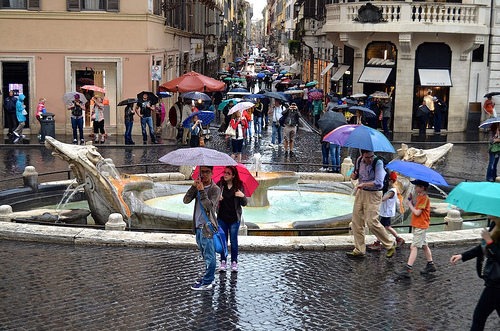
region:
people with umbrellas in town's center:
[86, 69, 443, 316]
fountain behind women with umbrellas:
[58, 139, 349, 280]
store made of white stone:
[307, 3, 478, 140]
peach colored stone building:
[10, 2, 186, 137]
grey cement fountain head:
[33, 129, 171, 236]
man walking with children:
[317, 123, 454, 276]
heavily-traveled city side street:
[190, 7, 330, 162]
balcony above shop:
[324, 1, 499, 71]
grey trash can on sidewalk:
[35, 111, 66, 148]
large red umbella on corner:
[149, 64, 239, 143]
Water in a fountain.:
[246, 141, 272, 180]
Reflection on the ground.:
[223, 246, 290, 329]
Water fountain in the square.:
[0, 134, 497, 251]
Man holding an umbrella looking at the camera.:
[159, 147, 223, 290]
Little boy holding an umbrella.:
[394, 157, 451, 276]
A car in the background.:
[239, 50, 261, 72]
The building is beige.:
[6, 5, 173, 136]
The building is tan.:
[316, 5, 498, 134]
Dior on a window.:
[76, 58, 111, 82]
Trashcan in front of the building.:
[31, 110, 66, 144]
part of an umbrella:
[205, 144, 208, 157]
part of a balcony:
[438, 15, 450, 66]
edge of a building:
[408, 70, 413, 102]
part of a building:
[80, 41, 114, 48]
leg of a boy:
[403, 250, 417, 265]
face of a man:
[366, 133, 378, 157]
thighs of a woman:
[225, 227, 239, 237]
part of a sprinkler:
[277, 173, 289, 199]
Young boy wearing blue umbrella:
[384, 158, 449, 284]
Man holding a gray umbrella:
[152, 142, 229, 299]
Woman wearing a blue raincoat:
[10, 89, 30, 141]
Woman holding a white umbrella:
[225, 100, 257, 165]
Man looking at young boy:
[344, 142, 401, 266]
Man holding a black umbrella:
[131, 87, 161, 148]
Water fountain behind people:
[127, 133, 361, 262]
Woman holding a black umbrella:
[112, 95, 139, 145]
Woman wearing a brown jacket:
[75, 77, 111, 144]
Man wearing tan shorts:
[277, 105, 303, 160]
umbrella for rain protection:
[159, 139, 226, 175]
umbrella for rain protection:
[326, 119, 392, 156]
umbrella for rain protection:
[377, 155, 442, 187]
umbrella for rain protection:
[448, 177, 499, 222]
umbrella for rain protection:
[83, 81, 103, 96]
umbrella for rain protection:
[183, 92, 210, 108]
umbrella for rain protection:
[116, 100, 140, 107]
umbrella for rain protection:
[308, 89, 320, 101]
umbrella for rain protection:
[226, 100, 251, 115]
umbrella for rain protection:
[252, 70, 267, 80]